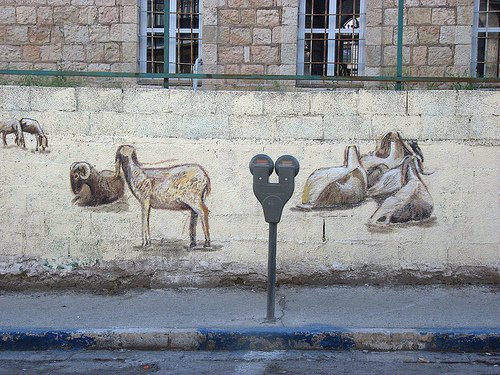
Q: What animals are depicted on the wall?
A: Sheep and seals.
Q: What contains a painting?
A: A wall.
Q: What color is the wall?
A: Cream.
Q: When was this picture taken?
A: Daytime.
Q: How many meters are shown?
A: Two.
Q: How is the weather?
A: Clear.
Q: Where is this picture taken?
A: A street.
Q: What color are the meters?
A: Black.